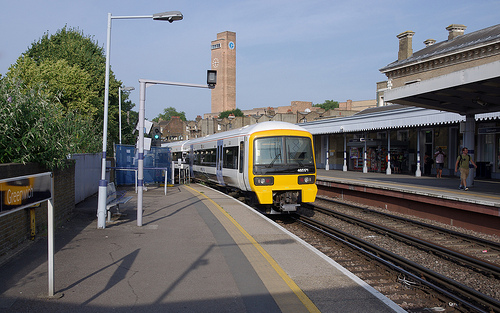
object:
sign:
[0, 171, 53, 219]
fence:
[116, 146, 171, 184]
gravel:
[403, 271, 499, 311]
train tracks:
[307, 199, 498, 306]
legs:
[461, 170, 467, 187]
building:
[210, 31, 237, 111]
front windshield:
[253, 136, 314, 174]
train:
[161, 121, 317, 215]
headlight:
[299, 176, 315, 184]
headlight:
[254, 176, 273, 185]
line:
[186, 183, 319, 313]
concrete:
[0, 239, 266, 312]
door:
[216, 140, 224, 185]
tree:
[4, 59, 95, 155]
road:
[77, 186, 308, 311]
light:
[154, 135, 158, 139]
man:
[455, 147, 477, 191]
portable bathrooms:
[113, 142, 171, 187]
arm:
[456, 156, 461, 166]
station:
[333, 26, 496, 205]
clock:
[212, 58, 219, 68]